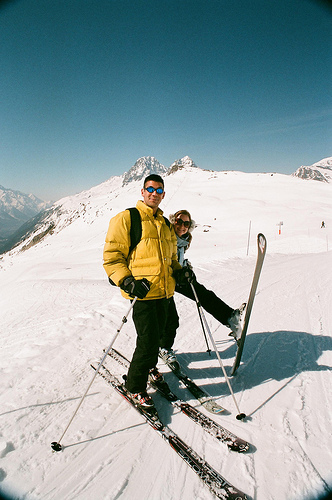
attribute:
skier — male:
[98, 166, 182, 405]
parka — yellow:
[98, 198, 181, 301]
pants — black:
[124, 294, 172, 394]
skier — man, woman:
[92, 173, 261, 408]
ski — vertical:
[222, 224, 303, 398]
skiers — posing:
[101, 174, 248, 409]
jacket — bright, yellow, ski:
[98, 199, 214, 317]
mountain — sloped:
[0, 152, 329, 249]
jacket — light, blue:
[176, 236, 187, 262]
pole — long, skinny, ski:
[45, 295, 142, 458]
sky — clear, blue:
[82, 11, 321, 150]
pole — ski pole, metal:
[146, 281, 276, 461]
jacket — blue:
[172, 230, 190, 273]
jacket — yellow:
[92, 190, 187, 297]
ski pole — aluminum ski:
[80, 276, 129, 456]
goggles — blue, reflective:
[142, 185, 166, 195]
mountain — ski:
[92, 121, 299, 207]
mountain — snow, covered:
[4, 190, 45, 236]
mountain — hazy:
[0, 172, 51, 248]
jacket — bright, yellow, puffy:
[102, 207, 181, 260]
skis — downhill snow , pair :
[227, 232, 276, 308]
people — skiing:
[102, 172, 247, 406]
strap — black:
[124, 211, 148, 246]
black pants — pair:
[120, 291, 201, 497]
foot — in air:
[228, 302, 247, 345]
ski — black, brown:
[144, 418, 251, 498]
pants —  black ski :
[174, 266, 237, 324]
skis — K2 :
[224, 231, 266, 371]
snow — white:
[0, 156, 331, 498]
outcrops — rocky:
[111, 133, 220, 206]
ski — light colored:
[159, 352, 225, 414]